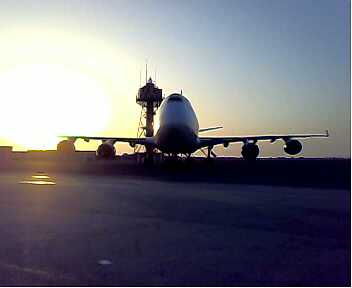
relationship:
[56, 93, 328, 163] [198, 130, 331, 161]
aircraft has wing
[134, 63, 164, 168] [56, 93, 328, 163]
tower behind aircraft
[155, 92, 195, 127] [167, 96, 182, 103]
compartment has window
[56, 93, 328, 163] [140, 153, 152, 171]
aircraft has wheel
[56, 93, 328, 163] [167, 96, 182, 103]
aircraft has window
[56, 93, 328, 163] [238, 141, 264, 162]
aircraft has motor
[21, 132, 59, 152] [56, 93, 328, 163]
sun at aircraft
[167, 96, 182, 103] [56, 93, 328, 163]
window at aircraft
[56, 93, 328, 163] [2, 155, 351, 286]
aircraft at tarmac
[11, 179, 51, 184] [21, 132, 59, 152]
reflection of sun